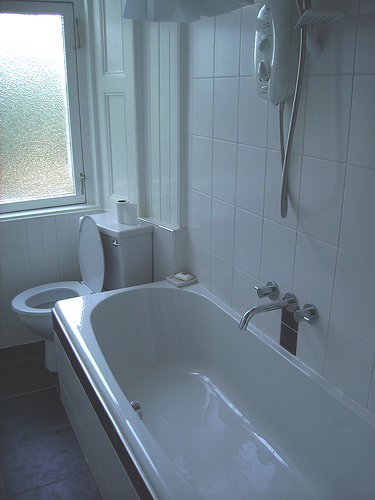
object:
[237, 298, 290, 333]
faucet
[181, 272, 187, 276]
bar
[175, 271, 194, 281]
soap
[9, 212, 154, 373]
toilet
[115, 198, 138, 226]
paper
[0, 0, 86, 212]
window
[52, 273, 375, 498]
bathtub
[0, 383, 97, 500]
tiles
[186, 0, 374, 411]
walls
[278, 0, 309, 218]
hose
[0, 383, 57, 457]
tile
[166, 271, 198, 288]
dish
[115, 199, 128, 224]
roll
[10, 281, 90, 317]
seat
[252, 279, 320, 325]
knobs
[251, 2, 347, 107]
shower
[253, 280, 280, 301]
tub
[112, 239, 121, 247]
handle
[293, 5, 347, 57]
head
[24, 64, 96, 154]
glass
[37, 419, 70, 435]
tile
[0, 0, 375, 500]
bathroom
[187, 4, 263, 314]
wall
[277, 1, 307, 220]
cord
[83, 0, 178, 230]
wood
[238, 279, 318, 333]
fixtures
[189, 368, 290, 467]
reflection